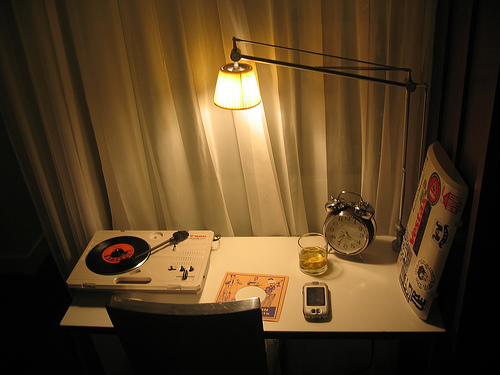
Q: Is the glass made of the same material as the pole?
A: No, the glass is made of glass and the pole is made of metal.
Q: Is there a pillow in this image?
A: No, there are no pillows.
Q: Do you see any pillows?
A: No, there are no pillows.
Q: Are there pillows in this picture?
A: No, there are no pillows.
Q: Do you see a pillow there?
A: No, there are no pillows.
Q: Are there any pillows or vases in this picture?
A: No, there are no pillows or vases.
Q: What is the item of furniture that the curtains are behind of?
A: The piece of furniture is a table.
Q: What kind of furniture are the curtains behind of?
A: The curtains are behind the table.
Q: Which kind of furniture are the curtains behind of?
A: The curtains are behind the table.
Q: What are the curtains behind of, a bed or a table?
A: The curtains are behind a table.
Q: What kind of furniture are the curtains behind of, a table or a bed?
A: The curtains are behind a table.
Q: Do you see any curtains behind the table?
A: Yes, there are curtains behind the table.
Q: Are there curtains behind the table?
A: Yes, there are curtains behind the table.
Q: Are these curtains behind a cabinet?
A: No, the curtains are behind the table.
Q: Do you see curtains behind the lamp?
A: Yes, there are curtains behind the lamp.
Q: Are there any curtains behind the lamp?
A: Yes, there are curtains behind the lamp.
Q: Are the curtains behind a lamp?
A: Yes, the curtains are behind a lamp.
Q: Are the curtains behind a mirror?
A: No, the curtains are behind a lamp.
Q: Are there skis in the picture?
A: No, there are no skis.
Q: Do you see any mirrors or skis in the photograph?
A: No, there are no skis or mirrors.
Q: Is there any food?
A: No, there is no food.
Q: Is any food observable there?
A: No, there is no food.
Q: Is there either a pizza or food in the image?
A: No, there are no food or pizzas.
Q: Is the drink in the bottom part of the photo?
A: Yes, the drink is in the bottom of the image.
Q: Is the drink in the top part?
A: No, the drink is in the bottom of the image.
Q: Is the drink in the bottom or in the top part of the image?
A: The drink is in the bottom of the image.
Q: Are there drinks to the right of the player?
A: Yes, there is a drink to the right of the player.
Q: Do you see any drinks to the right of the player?
A: Yes, there is a drink to the right of the player.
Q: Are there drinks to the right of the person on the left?
A: Yes, there is a drink to the right of the player.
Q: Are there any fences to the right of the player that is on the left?
A: No, there is a drink to the right of the player.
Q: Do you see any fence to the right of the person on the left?
A: No, there is a drink to the right of the player.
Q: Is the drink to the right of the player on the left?
A: Yes, the drink is to the right of the player.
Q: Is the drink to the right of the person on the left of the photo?
A: Yes, the drink is to the right of the player.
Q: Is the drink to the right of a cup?
A: No, the drink is to the right of the player.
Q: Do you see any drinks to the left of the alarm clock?
A: Yes, there is a drink to the left of the alarm clock.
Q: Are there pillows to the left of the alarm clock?
A: No, there is a drink to the left of the alarm clock.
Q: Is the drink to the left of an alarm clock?
A: Yes, the drink is to the left of an alarm clock.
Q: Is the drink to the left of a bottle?
A: No, the drink is to the left of an alarm clock.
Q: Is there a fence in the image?
A: No, there are no fences.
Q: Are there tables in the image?
A: Yes, there is a table.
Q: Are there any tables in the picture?
A: Yes, there is a table.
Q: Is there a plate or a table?
A: Yes, there is a table.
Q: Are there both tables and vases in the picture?
A: No, there is a table but no vases.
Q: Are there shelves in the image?
A: No, there are no shelves.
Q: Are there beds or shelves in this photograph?
A: No, there are no shelves or beds.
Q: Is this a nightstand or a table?
A: This is a table.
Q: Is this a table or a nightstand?
A: This is a table.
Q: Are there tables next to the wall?
A: Yes, there is a table next to the wall.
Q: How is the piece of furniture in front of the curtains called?
A: The piece of furniture is a table.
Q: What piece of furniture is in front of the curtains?
A: The piece of furniture is a table.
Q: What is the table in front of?
A: The table is in front of the curtains.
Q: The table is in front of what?
A: The table is in front of the curtains.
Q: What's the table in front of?
A: The table is in front of the curtains.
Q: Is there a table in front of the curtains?
A: Yes, there is a table in front of the curtains.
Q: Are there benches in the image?
A: No, there are no benches.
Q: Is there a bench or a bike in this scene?
A: No, there are no benches or bikes.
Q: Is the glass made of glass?
A: Yes, the glass is made of glass.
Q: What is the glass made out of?
A: The glass is made of glass.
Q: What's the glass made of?
A: The glass is made of glass.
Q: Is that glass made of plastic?
A: No, the glass is made of glass.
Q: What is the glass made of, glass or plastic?
A: The glass is made of glass.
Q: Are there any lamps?
A: Yes, there is a lamp.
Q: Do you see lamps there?
A: Yes, there is a lamp.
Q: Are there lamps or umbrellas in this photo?
A: Yes, there is a lamp.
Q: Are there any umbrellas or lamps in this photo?
A: Yes, there is a lamp.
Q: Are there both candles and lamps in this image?
A: No, there is a lamp but no candles.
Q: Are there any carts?
A: No, there are no carts.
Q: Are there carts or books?
A: No, there are no carts or books.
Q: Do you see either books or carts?
A: No, there are no carts or books.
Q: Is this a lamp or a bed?
A: This is a lamp.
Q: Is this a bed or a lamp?
A: This is a lamp.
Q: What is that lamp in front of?
A: The lamp is in front of the curtains.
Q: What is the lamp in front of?
A: The lamp is in front of the curtains.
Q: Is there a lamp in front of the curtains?
A: Yes, there is a lamp in front of the curtains.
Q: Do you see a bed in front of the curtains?
A: No, there is a lamp in front of the curtains.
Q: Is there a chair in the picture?
A: Yes, there is a chair.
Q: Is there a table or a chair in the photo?
A: Yes, there is a chair.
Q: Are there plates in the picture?
A: No, there are no plates.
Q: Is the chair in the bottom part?
A: Yes, the chair is in the bottom of the image.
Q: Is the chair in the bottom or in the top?
A: The chair is in the bottom of the image.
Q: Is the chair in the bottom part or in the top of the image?
A: The chair is in the bottom of the image.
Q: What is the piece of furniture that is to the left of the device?
A: The piece of furniture is a chair.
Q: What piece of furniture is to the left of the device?
A: The piece of furniture is a chair.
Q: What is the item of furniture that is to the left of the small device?
A: The piece of furniture is a chair.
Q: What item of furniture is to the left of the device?
A: The piece of furniture is a chair.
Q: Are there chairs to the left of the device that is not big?
A: Yes, there is a chair to the left of the device.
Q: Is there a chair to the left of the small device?
A: Yes, there is a chair to the left of the device.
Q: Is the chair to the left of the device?
A: Yes, the chair is to the left of the device.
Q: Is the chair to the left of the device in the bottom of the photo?
A: Yes, the chair is to the left of the device.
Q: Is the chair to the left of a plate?
A: No, the chair is to the left of the device.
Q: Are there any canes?
A: No, there are no canes.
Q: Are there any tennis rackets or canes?
A: No, there are no canes or tennis rackets.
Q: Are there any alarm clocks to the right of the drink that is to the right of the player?
A: Yes, there is an alarm clock to the right of the drink.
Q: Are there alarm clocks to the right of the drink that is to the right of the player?
A: Yes, there is an alarm clock to the right of the drink.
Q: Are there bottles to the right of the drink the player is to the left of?
A: No, there is an alarm clock to the right of the drink.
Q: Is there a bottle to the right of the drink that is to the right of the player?
A: No, there is an alarm clock to the right of the drink.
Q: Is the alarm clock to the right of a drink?
A: Yes, the alarm clock is to the right of a drink.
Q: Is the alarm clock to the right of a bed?
A: No, the alarm clock is to the right of a drink.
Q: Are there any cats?
A: No, there are no cats.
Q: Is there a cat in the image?
A: No, there are no cats.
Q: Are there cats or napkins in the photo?
A: No, there are no cats or napkins.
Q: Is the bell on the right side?
A: Yes, the bell is on the right of the image.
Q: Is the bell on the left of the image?
A: No, the bell is on the right of the image.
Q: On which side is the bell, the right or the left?
A: The bell is on the right of the image.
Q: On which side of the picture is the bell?
A: The bell is on the right of the image.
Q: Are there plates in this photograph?
A: No, there are no plates.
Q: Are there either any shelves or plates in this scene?
A: No, there are no plates or shelves.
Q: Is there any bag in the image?
A: No, there are no bags.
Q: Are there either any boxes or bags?
A: No, there are no bags or boxes.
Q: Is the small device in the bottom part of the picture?
A: Yes, the device is in the bottom of the image.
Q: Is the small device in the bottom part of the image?
A: Yes, the device is in the bottom of the image.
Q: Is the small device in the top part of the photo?
A: No, the device is in the bottom of the image.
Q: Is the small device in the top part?
A: No, the device is in the bottom of the image.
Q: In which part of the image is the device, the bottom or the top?
A: The device is in the bottom of the image.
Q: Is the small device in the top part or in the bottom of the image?
A: The device is in the bottom of the image.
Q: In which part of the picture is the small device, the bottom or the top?
A: The device is in the bottom of the image.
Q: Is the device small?
A: Yes, the device is small.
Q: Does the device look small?
A: Yes, the device is small.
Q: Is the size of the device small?
A: Yes, the device is small.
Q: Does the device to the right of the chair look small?
A: Yes, the device is small.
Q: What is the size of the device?
A: The device is small.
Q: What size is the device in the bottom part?
A: The device is small.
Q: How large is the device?
A: The device is small.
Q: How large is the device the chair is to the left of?
A: The device is small.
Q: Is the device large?
A: No, the device is small.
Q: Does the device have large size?
A: No, the device is small.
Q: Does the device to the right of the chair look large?
A: No, the device is small.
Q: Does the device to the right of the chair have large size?
A: No, the device is small.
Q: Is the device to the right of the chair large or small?
A: The device is small.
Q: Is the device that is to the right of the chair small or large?
A: The device is small.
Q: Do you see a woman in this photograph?
A: No, there are no women.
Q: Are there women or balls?
A: No, there are no women or balls.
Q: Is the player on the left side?
A: Yes, the player is on the left of the image.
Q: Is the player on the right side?
A: No, the player is on the left of the image.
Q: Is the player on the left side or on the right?
A: The player is on the left of the image.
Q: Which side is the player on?
A: The player is on the left of the image.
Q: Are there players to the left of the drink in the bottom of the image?
A: Yes, there is a player to the left of the drink.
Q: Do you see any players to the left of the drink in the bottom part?
A: Yes, there is a player to the left of the drink.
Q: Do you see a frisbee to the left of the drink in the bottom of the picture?
A: No, there is a player to the left of the drink.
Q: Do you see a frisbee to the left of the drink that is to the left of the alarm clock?
A: No, there is a player to the left of the drink.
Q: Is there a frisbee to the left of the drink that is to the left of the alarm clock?
A: No, there is a player to the left of the drink.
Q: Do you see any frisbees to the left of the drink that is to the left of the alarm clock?
A: No, there is a player to the left of the drink.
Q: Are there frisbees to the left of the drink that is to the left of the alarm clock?
A: No, there is a player to the left of the drink.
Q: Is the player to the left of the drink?
A: Yes, the player is to the left of the drink.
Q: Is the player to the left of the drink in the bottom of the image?
A: Yes, the player is to the left of the drink.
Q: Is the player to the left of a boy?
A: No, the player is to the left of the drink.